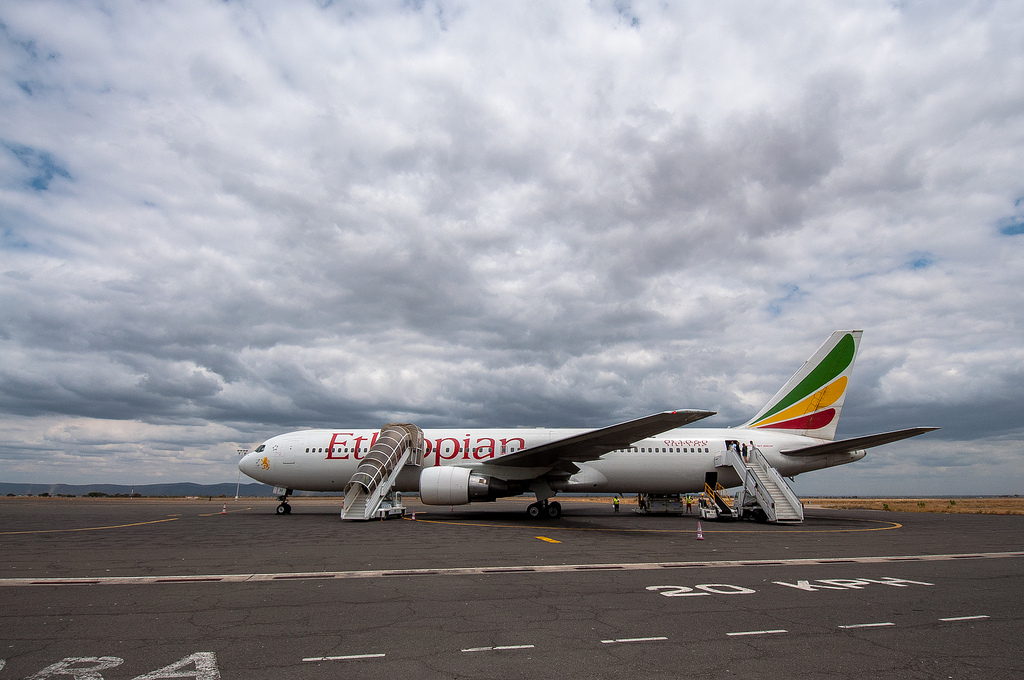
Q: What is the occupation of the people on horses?
A: Police.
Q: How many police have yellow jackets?
A: Two.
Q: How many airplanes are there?
A: One.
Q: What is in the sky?
A: Clouds.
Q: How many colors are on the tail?
A: Three.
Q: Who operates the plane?
A: Pilot.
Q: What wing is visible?
A: Left.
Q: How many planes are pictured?
A: One.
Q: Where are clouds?
A: In the sky.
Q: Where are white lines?
A: On the tarmac.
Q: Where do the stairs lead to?
A: Inside the plane.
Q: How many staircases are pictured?
A: Two.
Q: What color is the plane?
A: Mostly white.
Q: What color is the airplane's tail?
A: Green, yellow and red.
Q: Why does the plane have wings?
A: To fly.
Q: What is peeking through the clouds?
A: The sky.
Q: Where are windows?
A: On the plane.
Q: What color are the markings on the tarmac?
A: White.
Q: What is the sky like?
A: Overcast.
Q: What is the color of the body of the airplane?
A: White.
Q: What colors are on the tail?
A: Red, yellow, and green.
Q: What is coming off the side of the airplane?
A: Stairs.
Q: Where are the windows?
A: On the side of the airplane.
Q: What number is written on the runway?
A: 20.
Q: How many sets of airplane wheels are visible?
A: Two.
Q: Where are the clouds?
A: Sky.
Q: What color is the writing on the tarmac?
A: White.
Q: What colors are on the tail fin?
A: Green, yellow and red.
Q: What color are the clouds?
A: White.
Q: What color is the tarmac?
A: Black.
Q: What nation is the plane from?
A: Ethiopia.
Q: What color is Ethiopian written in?
A: Red.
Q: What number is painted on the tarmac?
A: 20.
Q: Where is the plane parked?
A: Tarmac.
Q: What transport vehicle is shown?
A: Plane.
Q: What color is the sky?
A: Blue.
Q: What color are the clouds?
A: White.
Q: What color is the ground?
A: Gray.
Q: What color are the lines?
A: White.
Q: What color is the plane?
A: White.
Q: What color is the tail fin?
A: Green.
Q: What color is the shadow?
A: Black.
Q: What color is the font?
A: Red.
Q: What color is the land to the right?
A: Brown.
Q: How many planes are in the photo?
A: One.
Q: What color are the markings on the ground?
A: White.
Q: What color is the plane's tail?
A: Green, yellow and red.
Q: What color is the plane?
A: White.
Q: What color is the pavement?
A: Dark gray.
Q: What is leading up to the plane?
A: Stairs.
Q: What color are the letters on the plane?
A: Red.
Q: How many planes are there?
A: One.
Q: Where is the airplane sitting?
A: Runway.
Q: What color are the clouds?
A: White.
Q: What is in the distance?
A: Field.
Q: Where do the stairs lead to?
A: Inside the plane.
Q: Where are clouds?
A: In the sky.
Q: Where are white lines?
A: On the tarmac.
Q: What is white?
A: Clouds.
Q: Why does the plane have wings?
A: To fly.